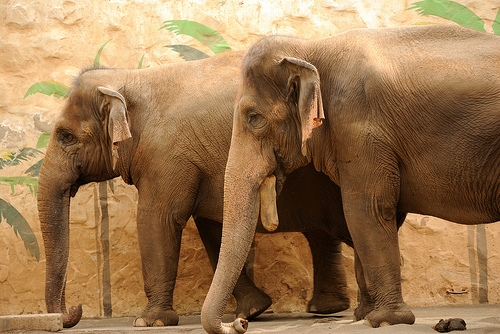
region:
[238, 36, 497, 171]
this is an elephant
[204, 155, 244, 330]
this is the trunk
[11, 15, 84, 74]
this is a wall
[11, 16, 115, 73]
the wall is brown in color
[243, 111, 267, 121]
this is the eye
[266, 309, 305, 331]
this is the ground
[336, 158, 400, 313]
this is the leg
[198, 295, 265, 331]
the trunk is touching the ground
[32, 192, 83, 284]
the trunk is long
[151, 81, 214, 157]
the elephant is brown in color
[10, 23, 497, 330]
two elephants standing side by side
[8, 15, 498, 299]
rock walk behind elepahtns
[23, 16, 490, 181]
green leaves painted on wall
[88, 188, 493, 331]
tree trunks painted on wall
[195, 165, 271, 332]
elephant with trunk touching the ground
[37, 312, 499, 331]
paved ground elephants are walking on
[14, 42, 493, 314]
two elephants standing in front of painted rock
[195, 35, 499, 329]
elephants standing further back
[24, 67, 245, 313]
elephants walking slighlt in front of other elephant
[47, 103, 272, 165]
eyes of two gray elephants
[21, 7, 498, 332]
Two elephants walking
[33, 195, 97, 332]
Trunk of the elephant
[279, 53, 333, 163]
A huge ear shaped like africa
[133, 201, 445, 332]
Legs of the elephant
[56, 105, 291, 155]
Eyes of the elephant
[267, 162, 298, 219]
Mouth of the elephant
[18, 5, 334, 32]
Walls near the elephant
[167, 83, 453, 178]
Grey color wrinkled skin of the elephant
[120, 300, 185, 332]
Front feet of the elephant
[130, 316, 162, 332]
Nails of the elephant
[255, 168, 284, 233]
elephant's tongue is out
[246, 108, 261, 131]
eye of an elephant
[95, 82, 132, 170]
elephant's ear is large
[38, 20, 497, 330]
two elephants standing near each other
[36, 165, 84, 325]
elephant has large trunk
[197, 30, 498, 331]
elephant is brown in color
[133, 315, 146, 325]
the nail of an elephant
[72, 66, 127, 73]
tiny hairs on top of elephant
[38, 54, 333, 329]
elephant is walking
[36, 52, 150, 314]
a tree painted on the wall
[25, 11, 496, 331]
two elephants side-by-side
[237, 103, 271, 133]
eye of elephant is small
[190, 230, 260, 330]
tip of trunk is over the ground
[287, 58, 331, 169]
border of ear is pink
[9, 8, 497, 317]
elephants are in front of yellow wall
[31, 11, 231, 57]
green leaves painted on wall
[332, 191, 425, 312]
front legs of elephant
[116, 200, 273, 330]
front legs of elephant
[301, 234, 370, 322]
back legs of elephant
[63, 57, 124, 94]
hair on head of elephant